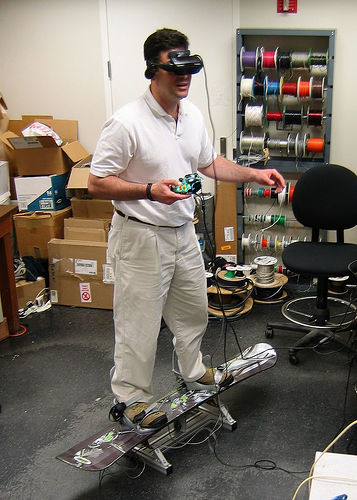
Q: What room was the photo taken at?
A: It was taken at the office.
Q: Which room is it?
A: It is an office.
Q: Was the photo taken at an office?
A: Yes, it was taken in an office.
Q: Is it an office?
A: Yes, it is an office.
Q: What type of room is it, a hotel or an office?
A: It is an office.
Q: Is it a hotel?
A: No, it is an office.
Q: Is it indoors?
A: Yes, it is indoors.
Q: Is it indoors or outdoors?
A: It is indoors.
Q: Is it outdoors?
A: No, it is indoors.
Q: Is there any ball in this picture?
A: No, there are no balls.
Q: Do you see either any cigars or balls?
A: No, there are no balls or cigars.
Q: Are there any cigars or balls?
A: No, there are no balls or cigars.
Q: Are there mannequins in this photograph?
A: No, there are no mannequins.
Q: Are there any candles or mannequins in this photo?
A: No, there are no mannequins or candles.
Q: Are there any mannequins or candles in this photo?
A: No, there are no mannequins or candles.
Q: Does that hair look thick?
A: Yes, the hair is thick.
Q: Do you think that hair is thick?
A: Yes, the hair is thick.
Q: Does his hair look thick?
A: Yes, the hair is thick.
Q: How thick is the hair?
A: The hair is thick.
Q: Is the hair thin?
A: No, the hair is thick.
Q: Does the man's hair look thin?
A: No, the hair is thick.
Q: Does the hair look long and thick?
A: Yes, the hair is long and thick.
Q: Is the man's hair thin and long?
A: No, the hair is long but thick.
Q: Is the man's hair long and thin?
A: No, the hair is long but thick.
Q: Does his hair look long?
A: Yes, the hair is long.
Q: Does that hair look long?
A: Yes, the hair is long.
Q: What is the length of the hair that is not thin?
A: The hair is long.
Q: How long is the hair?
A: The hair is long.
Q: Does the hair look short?
A: No, the hair is long.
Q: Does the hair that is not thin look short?
A: No, the hair is long.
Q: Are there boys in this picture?
A: No, there are no boys.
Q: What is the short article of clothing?
A: The clothing item is a shirt.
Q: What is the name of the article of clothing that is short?
A: The clothing item is a shirt.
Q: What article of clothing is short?
A: The clothing item is a shirt.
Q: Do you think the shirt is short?
A: Yes, the shirt is short.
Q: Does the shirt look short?
A: Yes, the shirt is short.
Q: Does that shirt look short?
A: Yes, the shirt is short.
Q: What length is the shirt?
A: The shirt is short.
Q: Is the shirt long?
A: No, the shirt is short.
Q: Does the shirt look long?
A: No, the shirt is short.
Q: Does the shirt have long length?
A: No, the shirt is short.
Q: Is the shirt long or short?
A: The shirt is short.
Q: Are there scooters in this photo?
A: No, there are no scooters.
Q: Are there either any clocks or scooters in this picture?
A: No, there are no scooters or clocks.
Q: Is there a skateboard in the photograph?
A: Yes, there is a skateboard.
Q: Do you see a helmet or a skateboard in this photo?
A: Yes, there is a skateboard.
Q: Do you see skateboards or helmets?
A: Yes, there is a skateboard.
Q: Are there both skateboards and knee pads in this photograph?
A: No, there is a skateboard but no knee pads.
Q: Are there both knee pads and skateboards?
A: No, there is a skateboard but no knee pads.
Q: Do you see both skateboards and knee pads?
A: No, there is a skateboard but no knee pads.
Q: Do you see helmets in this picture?
A: No, there are no helmets.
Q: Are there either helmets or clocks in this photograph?
A: No, there are no helmets or clocks.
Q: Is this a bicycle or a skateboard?
A: This is a skateboard.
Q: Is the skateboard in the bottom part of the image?
A: Yes, the skateboard is in the bottom of the image.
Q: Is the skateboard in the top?
A: No, the skateboard is in the bottom of the image.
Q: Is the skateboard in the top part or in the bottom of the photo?
A: The skateboard is in the bottom of the image.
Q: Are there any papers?
A: No, there are no papers.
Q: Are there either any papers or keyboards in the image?
A: No, there are no papers or keyboards.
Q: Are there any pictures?
A: No, there are no pictures.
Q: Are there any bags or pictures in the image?
A: No, there are no pictures or bags.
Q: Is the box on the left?
A: Yes, the box is on the left of the image.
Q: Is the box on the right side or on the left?
A: The box is on the left of the image.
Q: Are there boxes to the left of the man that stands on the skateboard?
A: Yes, there is a box to the left of the man.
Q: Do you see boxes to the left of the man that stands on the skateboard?
A: Yes, there is a box to the left of the man.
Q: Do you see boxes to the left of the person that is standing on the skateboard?
A: Yes, there is a box to the left of the man.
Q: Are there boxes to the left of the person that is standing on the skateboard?
A: Yes, there is a box to the left of the man.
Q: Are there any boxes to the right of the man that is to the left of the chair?
A: No, the box is to the left of the man.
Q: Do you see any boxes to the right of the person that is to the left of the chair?
A: No, the box is to the left of the man.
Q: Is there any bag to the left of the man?
A: No, there is a box to the left of the man.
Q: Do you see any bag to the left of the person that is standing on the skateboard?
A: No, there is a box to the left of the man.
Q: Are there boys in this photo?
A: No, there are no boys.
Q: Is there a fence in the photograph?
A: No, there are no fences.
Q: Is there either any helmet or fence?
A: No, there are no fences or helmets.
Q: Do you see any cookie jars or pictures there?
A: No, there are no pictures or cookie jars.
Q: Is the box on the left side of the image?
A: Yes, the box is on the left of the image.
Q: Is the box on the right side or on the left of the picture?
A: The box is on the left of the image.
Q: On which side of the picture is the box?
A: The box is on the left of the image.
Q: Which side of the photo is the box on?
A: The box is on the left of the image.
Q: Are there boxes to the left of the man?
A: Yes, there is a box to the left of the man.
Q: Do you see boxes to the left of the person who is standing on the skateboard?
A: Yes, there is a box to the left of the man.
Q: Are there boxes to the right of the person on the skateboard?
A: No, the box is to the left of the man.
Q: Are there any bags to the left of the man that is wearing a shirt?
A: No, there is a box to the left of the man.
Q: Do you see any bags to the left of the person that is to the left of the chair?
A: No, there is a box to the left of the man.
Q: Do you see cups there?
A: No, there are no cups.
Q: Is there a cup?
A: No, there are no cups.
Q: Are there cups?
A: No, there are no cups.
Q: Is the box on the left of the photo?
A: Yes, the box is on the left of the image.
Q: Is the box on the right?
A: No, the box is on the left of the image.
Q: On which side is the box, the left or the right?
A: The box is on the left of the image.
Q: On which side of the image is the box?
A: The box is on the left of the image.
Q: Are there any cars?
A: No, there are no cars.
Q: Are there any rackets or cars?
A: No, there are no cars or rackets.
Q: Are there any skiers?
A: No, there are no skiers.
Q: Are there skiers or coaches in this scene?
A: No, there are no skiers or coaches.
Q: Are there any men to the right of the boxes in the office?
A: Yes, there is a man to the right of the boxes.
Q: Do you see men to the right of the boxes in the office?
A: Yes, there is a man to the right of the boxes.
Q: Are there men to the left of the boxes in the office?
A: No, the man is to the right of the boxes.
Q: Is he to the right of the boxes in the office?
A: Yes, the man is to the right of the boxes.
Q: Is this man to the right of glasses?
A: No, the man is to the right of the boxes.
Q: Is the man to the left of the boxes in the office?
A: No, the man is to the right of the boxes.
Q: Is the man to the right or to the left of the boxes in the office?
A: The man is to the right of the boxes.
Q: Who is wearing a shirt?
A: The man is wearing a shirt.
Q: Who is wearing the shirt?
A: The man is wearing a shirt.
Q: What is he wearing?
A: The man is wearing a shirt.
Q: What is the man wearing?
A: The man is wearing a shirt.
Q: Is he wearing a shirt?
A: Yes, the man is wearing a shirt.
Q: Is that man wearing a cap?
A: No, the man is wearing a shirt.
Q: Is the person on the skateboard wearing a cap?
A: No, the man is wearing a shirt.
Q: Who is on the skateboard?
A: The man is on the skateboard.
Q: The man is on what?
A: The man is on the skateboard.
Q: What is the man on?
A: The man is on the skateboard.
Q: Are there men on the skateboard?
A: Yes, there is a man on the skateboard.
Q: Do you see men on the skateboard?
A: Yes, there is a man on the skateboard.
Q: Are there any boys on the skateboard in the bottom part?
A: No, there is a man on the skateboard.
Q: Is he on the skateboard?
A: Yes, the man is on the skateboard.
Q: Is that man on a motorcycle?
A: No, the man is on the skateboard.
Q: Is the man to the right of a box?
A: Yes, the man is to the right of a box.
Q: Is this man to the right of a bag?
A: No, the man is to the right of a box.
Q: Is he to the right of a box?
A: Yes, the man is to the right of a box.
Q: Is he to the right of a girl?
A: No, the man is to the right of a box.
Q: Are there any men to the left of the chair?
A: Yes, there is a man to the left of the chair.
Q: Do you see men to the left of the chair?
A: Yes, there is a man to the left of the chair.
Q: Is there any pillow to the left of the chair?
A: No, there is a man to the left of the chair.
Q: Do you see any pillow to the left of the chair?
A: No, there is a man to the left of the chair.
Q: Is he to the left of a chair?
A: Yes, the man is to the left of a chair.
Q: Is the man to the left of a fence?
A: No, the man is to the left of a chair.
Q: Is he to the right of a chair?
A: No, the man is to the left of a chair.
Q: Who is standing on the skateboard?
A: The man is standing on the skateboard.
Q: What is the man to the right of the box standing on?
A: The man is standing on the skateboard.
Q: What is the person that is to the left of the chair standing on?
A: The man is standing on the skateboard.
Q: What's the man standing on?
A: The man is standing on the skateboard.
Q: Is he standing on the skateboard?
A: Yes, the man is standing on the skateboard.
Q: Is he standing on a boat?
A: No, the man is standing on the skateboard.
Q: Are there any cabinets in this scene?
A: Yes, there is a cabinet.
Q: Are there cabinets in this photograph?
A: Yes, there is a cabinet.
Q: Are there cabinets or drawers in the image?
A: Yes, there is a cabinet.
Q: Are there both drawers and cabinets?
A: No, there is a cabinet but no drawers.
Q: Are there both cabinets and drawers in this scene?
A: No, there is a cabinet but no drawers.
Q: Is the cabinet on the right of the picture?
A: Yes, the cabinet is on the right of the image.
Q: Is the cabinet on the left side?
A: No, the cabinet is on the right of the image.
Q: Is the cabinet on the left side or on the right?
A: The cabinet is on the right of the image.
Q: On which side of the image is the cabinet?
A: The cabinet is on the right of the image.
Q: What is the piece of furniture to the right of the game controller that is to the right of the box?
A: The piece of furniture is a cabinet.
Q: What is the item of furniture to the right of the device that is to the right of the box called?
A: The piece of furniture is a cabinet.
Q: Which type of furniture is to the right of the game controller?
A: The piece of furniture is a cabinet.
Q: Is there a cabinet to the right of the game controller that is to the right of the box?
A: Yes, there is a cabinet to the right of the game controller.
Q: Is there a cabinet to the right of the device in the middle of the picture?
A: Yes, there is a cabinet to the right of the game controller.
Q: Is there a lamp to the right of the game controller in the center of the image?
A: No, there is a cabinet to the right of the game controller.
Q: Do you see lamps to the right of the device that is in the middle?
A: No, there is a cabinet to the right of the game controller.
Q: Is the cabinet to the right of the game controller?
A: Yes, the cabinet is to the right of the game controller.